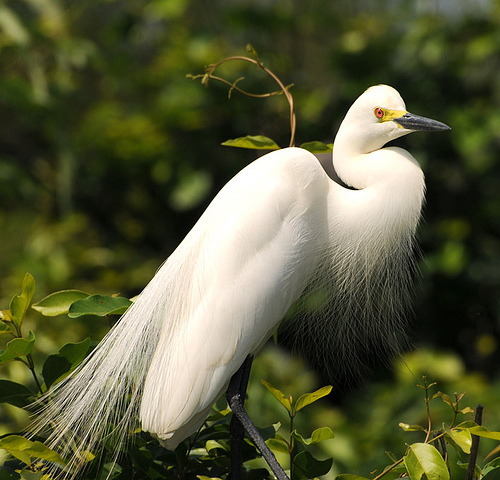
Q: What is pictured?
A: Bird.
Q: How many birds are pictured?
A: 1.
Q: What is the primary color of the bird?
A: White.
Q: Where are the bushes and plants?
A: Behind the bird.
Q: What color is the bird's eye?
A: Orange.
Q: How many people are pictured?
A: Zero.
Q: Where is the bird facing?
A: Right.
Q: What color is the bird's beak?
A: Black.